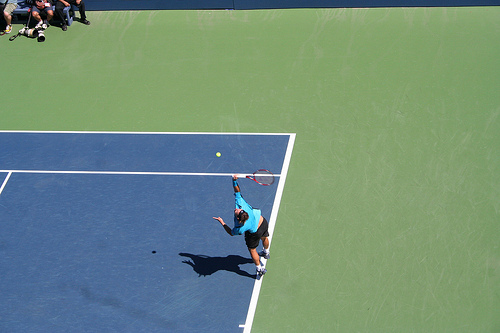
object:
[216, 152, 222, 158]
ball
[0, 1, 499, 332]
air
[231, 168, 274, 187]
racket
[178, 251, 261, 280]
shadow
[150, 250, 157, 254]
shadow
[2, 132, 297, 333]
court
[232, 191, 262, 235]
shirt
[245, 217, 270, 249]
shorts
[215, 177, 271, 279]
man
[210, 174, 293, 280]
motion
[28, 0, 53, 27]
people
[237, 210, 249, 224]
hair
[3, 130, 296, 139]
line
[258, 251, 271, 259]
shoe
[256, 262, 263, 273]
socks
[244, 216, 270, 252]
pants